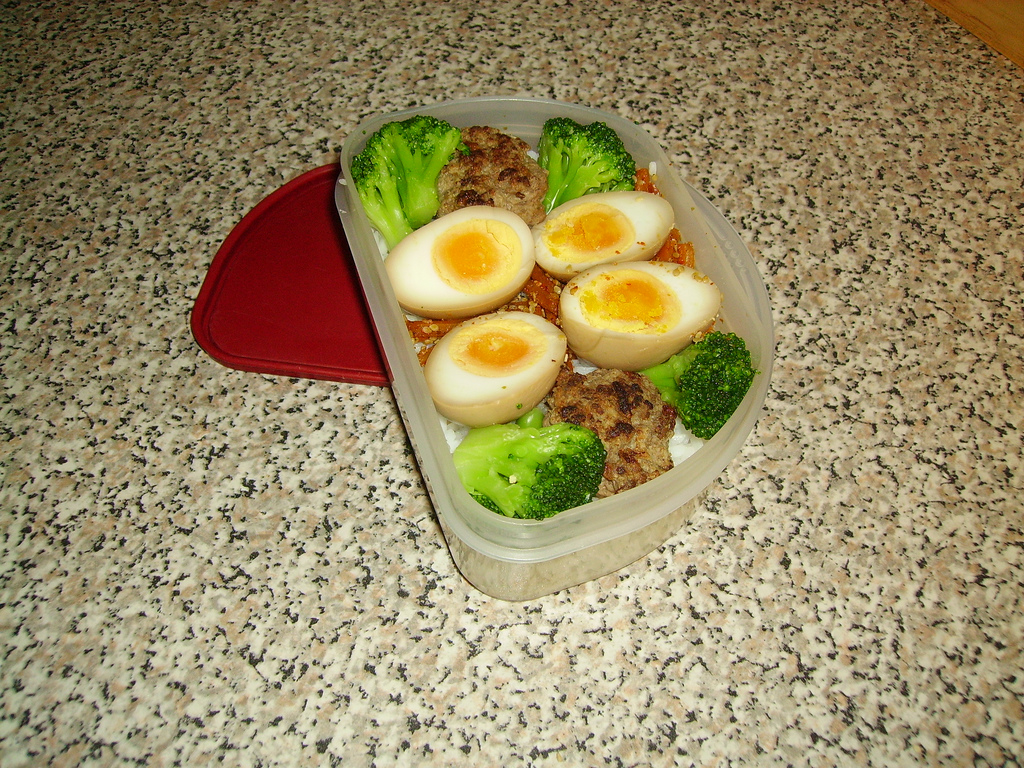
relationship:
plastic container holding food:
[329, 89, 777, 602] [385, 119, 675, 470]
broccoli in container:
[336, 113, 453, 250] [330, 85, 905, 569]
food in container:
[375, 150, 710, 496] [313, 113, 888, 680]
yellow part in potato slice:
[441, 232, 511, 289] [387, 206, 513, 315]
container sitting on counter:
[289, 106, 767, 603] [17, 394, 385, 755]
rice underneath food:
[668, 433, 703, 466] [385, 161, 712, 473]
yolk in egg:
[473, 323, 525, 365] [439, 309, 558, 426]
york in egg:
[579, 258, 662, 334] [549, 268, 725, 353]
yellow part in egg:
[441, 219, 520, 288] [395, 195, 530, 325]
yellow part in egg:
[441, 219, 520, 288] [382, 202, 532, 321]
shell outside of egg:
[499, 387, 543, 407] [423, 305, 564, 435]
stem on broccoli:
[449, 428, 504, 478] [462, 422, 584, 524]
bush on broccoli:
[538, 426, 584, 509] [454, 424, 586, 522]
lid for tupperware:
[259, 242, 331, 348] [478, 519, 613, 587]